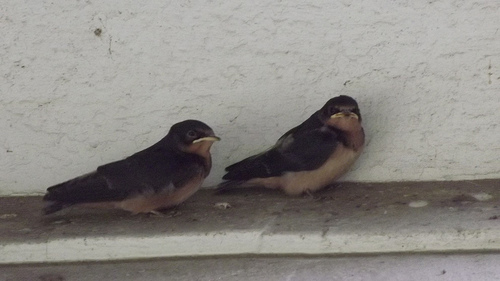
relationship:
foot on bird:
[147, 205, 173, 224] [52, 114, 239, 221]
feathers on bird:
[280, 132, 296, 150] [253, 64, 374, 206]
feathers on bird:
[215, 164, 245, 193] [253, 64, 374, 206]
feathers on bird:
[338, 95, 357, 104] [253, 64, 374, 206]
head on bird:
[325, 95, 362, 133] [243, 99, 484, 154]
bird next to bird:
[213, 94, 366, 197] [49, 118, 220, 224]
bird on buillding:
[213, 94, 366, 197] [0, 0, 500, 281]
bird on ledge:
[231, 76, 362, 208] [6, 154, 487, 271]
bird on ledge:
[43, 117, 230, 231] [6, 154, 487, 271]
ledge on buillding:
[1, 167, 494, 267] [24, 17, 465, 258]